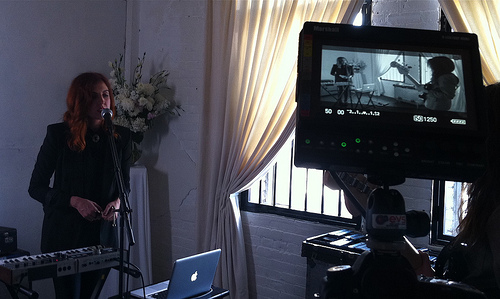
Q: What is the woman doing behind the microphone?
A: Singing.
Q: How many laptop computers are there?
A: One.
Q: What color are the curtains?
A: Off white.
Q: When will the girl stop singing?
A: When she is finished recording.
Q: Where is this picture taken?
A: In a studio inside of a building.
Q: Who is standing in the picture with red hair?
A: A woman.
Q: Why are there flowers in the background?
A: For decoration purposes.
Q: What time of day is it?
A: Daytime.